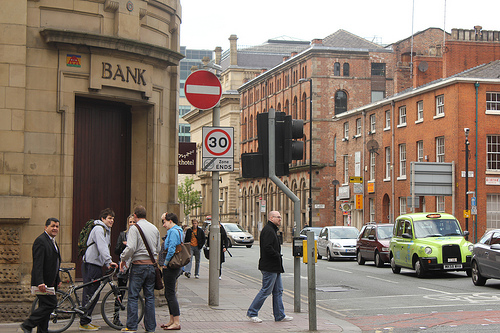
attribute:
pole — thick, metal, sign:
[208, 180, 219, 306]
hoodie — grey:
[80, 217, 115, 268]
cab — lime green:
[384, 204, 469, 288]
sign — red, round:
[172, 51, 246, 129]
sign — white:
[201, 125, 235, 175]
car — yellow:
[375, 194, 497, 299]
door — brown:
[71, 92, 131, 279]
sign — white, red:
[183, 65, 225, 125]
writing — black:
[185, 122, 247, 169]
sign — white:
[173, 98, 257, 203]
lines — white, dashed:
[324, 264, 465, 296]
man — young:
[74, 209, 116, 319]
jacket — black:
[256, 222, 286, 274]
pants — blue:
[246, 270, 288, 318]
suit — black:
[30, 232, 57, 322]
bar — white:
[187, 84, 222, 94]